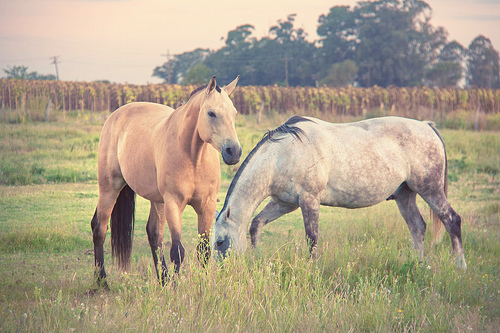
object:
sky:
[1, 0, 221, 39]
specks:
[334, 147, 371, 194]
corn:
[0, 82, 497, 110]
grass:
[21, 186, 51, 239]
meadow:
[0, 78, 500, 333]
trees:
[153, 9, 500, 86]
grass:
[348, 240, 439, 295]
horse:
[89, 74, 243, 297]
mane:
[251, 115, 308, 152]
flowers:
[196, 229, 214, 252]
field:
[0, 78, 500, 333]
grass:
[170, 276, 287, 325]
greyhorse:
[214, 115, 467, 279]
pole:
[51, 55, 60, 82]